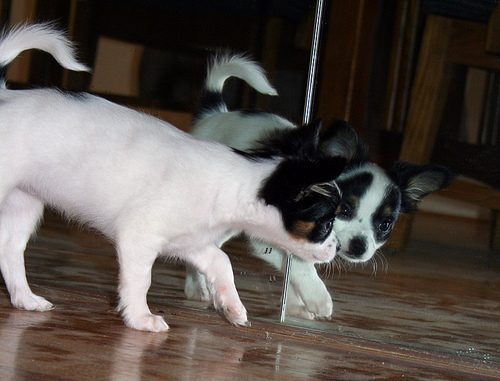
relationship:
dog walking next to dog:
[183, 48, 458, 323] [237, 75, 447, 299]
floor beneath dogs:
[1, 198, 498, 378] [183, 50, 456, 322]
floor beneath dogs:
[1, 198, 498, 378] [1, 18, 346, 335]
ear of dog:
[396, 160, 460, 210] [178, 55, 462, 321]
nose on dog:
[347, 236, 367, 257] [178, 55, 462, 321]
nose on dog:
[334, 241, 342, 252] [2, 19, 336, 339]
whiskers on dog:
[354, 230, 392, 277] [189, 58, 406, 322]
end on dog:
[2, 22, 93, 73] [2, 19, 336, 339]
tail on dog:
[193, 49, 284, 112] [183, 44, 476, 331]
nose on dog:
[336, 241, 341, 252] [2, 19, 336, 339]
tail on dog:
[200, 49, 284, 113] [194, 37, 461, 322]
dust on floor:
[21, 327, 97, 374] [0, 286, 493, 379]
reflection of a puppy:
[200, 57, 458, 322] [0, 20, 346, 333]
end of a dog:
[2, 22, 72, 232] [0, 19, 352, 335]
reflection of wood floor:
[271, 258, 484, 325] [3, 334, 356, 380]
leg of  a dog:
[108, 234, 175, 346] [3, 30, 472, 317]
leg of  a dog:
[0, 194, 55, 311] [2, 19, 336, 339]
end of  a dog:
[2, 22, 93, 73] [2, 19, 336, 339]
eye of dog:
[312, 211, 337, 243] [2, 19, 336, 339]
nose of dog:
[341, 234, 376, 262] [2, 19, 336, 339]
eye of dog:
[373, 214, 393, 236] [32, 26, 447, 351]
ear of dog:
[398, 160, 468, 229] [191, 40, 416, 335]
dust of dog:
[21, 327, 97, 374] [178, 55, 462, 321]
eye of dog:
[377, 221, 392, 234] [178, 55, 462, 321]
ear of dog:
[280, 152, 347, 199] [2, 19, 336, 339]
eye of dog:
[376, 213, 395, 238] [2, 19, 336, 339]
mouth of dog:
[306, 248, 330, 265] [2, 19, 336, 339]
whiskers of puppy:
[366, 247, 391, 281] [175, 44, 466, 329]